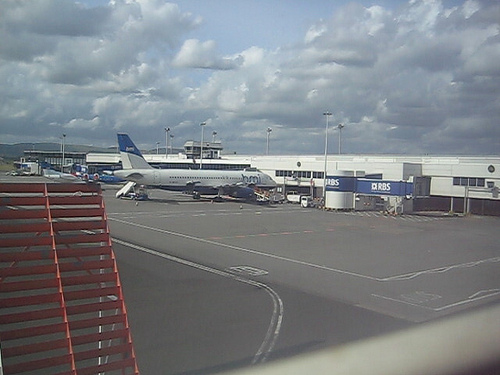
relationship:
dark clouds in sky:
[0, 0, 500, 148] [220, 7, 273, 32]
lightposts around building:
[196, 119, 207, 162] [86, 147, 494, 215]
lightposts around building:
[321, 107, 331, 206] [86, 147, 494, 215]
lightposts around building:
[163, 122, 170, 160] [86, 147, 494, 215]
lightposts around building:
[58, 132, 65, 176] [86, 147, 494, 215]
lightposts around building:
[265, 125, 272, 157] [86, 147, 494, 215]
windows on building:
[272, 165, 330, 185] [253, 156, 377, 196]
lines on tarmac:
[105, 207, 500, 366] [1, 146, 497, 372]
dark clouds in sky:
[0, 0, 500, 148] [102, 22, 353, 63]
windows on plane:
[168, 174, 241, 181] [111, 131, 276, 201]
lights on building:
[322, 112, 331, 159] [86, 147, 494, 215]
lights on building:
[336, 123, 344, 151] [86, 147, 494, 215]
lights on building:
[264, 126, 271, 155] [86, 147, 494, 215]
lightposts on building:
[199, 121, 207, 169] [86, 147, 494, 215]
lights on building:
[210, 130, 216, 148] [86, 147, 494, 215]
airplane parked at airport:
[112, 131, 281, 199] [3, 140, 495, 373]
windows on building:
[275, 169, 326, 179] [86, 147, 494, 215]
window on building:
[474, 179, 484, 188] [80, 153, 498, 218]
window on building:
[465, 178, 475, 186] [80, 153, 498, 218]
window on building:
[457, 179, 468, 187] [80, 153, 498, 218]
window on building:
[451, 177, 460, 186] [80, 153, 498, 218]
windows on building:
[275, 169, 326, 179] [80, 153, 498, 218]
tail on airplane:
[117, 131, 153, 169] [111, 130, 275, 200]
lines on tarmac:
[105, 207, 500, 366] [141, 210, 481, 365]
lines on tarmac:
[105, 207, 500, 366] [95, 184, 497, 373]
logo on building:
[325, 178, 392, 194] [87, 140, 499, 212]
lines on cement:
[122, 211, 482, 308] [8, 168, 496, 373]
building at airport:
[80, 153, 498, 218] [3, 140, 495, 373]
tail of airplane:
[117, 131, 153, 169] [112, 131, 281, 199]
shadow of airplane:
[138, 196, 255, 206] [111, 130, 275, 200]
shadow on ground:
[138, 196, 255, 206] [91, 185, 498, 372]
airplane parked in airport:
[111, 130, 275, 200] [3, 140, 495, 373]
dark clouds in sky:
[0, 0, 500, 148] [6, 0, 493, 167]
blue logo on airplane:
[237, 171, 264, 188] [112, 131, 281, 199]